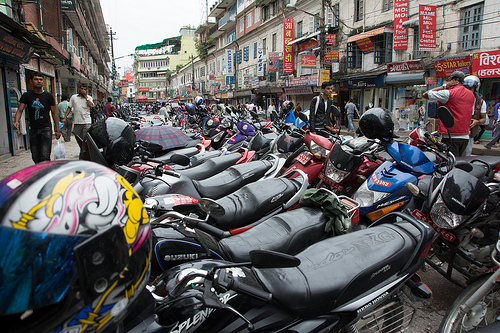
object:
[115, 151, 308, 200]
motorcycle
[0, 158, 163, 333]
helmet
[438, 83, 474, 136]
vest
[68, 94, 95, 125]
shirt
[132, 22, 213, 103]
building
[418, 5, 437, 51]
sign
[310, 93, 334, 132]
coat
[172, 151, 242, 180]
seat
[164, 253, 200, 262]
logo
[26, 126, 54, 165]
pants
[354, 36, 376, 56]
signs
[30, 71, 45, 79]
hair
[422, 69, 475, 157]
man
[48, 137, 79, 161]
bag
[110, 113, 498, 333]
row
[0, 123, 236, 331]
foreground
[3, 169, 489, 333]
motorbikes